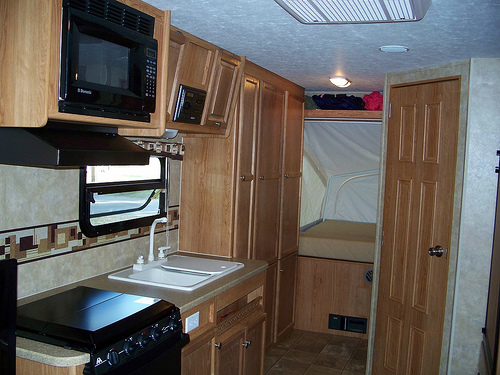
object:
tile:
[286, 324, 363, 366]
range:
[17, 282, 191, 374]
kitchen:
[2, 0, 495, 373]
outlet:
[183, 309, 200, 332]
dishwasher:
[16, 283, 184, 373]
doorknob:
[424, 236, 443, 258]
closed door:
[369, 78, 463, 371]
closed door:
[237, 82, 260, 257]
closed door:
[257, 79, 284, 258]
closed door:
[281, 83, 303, 330]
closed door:
[245, 318, 265, 371]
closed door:
[208, 330, 244, 372]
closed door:
[207, 57, 240, 122]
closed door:
[171, 46, 210, 117]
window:
[84, 156, 166, 232]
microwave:
[62, 16, 159, 114]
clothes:
[322, 92, 381, 107]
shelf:
[300, 102, 382, 119]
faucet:
[134, 216, 174, 268]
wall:
[2, 125, 179, 255]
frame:
[77, 150, 168, 238]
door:
[365, 87, 497, 352]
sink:
[122, 248, 229, 298]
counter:
[84, 245, 272, 302]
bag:
[316, 90, 394, 116]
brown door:
[372, 80, 458, 373]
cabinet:
[234, 74, 254, 256]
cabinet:
[262, 85, 281, 258]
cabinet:
[278, 94, 302, 254]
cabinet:
[277, 260, 296, 335]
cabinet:
[265, 265, 275, 347]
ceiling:
[191, 2, 489, 59]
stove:
[22, 269, 187, 373]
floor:
[270, 327, 373, 366]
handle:
[424, 242, 450, 259]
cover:
[83, 166, 174, 226]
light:
[323, 62, 353, 91]